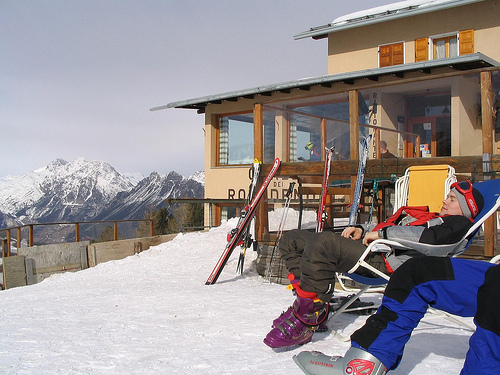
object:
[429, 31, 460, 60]
window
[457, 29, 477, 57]
shutters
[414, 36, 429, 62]
shutters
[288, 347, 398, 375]
boots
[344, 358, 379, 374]
design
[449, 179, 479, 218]
goggles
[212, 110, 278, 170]
window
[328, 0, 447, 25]
snow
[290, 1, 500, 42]
roof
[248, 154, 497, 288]
frame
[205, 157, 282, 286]
skis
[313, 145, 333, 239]
skis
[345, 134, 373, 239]
skis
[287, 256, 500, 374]
person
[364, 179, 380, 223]
ski poles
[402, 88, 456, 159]
doorway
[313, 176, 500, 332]
chair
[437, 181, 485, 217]
head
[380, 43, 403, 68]
shutters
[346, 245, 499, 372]
ski pants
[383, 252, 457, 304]
patch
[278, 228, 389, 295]
black pants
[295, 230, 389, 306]
legs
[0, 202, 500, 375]
snow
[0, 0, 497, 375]
picture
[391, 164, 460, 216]
chairs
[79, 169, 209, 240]
mountains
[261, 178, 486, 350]
man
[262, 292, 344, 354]
purple skates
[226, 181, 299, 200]
building print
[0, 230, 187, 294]
stone base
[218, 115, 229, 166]
curtains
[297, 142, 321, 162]
person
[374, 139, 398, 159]
person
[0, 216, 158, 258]
fence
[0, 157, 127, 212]
snow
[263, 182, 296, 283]
poles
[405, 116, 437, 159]
doors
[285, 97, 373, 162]
windows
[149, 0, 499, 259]
building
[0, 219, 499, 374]
ground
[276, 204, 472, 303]
ski outfit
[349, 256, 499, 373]
ski outfit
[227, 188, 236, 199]
word